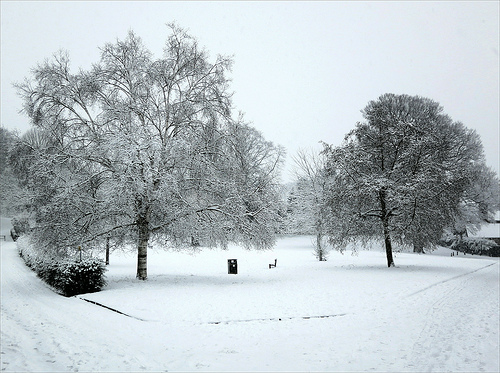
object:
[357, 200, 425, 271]
branch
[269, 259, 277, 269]
bench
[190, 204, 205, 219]
branch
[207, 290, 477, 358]
snow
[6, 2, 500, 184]
sky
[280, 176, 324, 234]
tree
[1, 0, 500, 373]
out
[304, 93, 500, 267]
tree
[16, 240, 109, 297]
bush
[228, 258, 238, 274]
can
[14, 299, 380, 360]
snow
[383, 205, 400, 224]
branch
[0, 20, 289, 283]
tree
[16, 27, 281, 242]
snow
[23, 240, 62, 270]
snow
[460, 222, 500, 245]
house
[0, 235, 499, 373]
ground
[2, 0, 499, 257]
background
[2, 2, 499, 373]
photo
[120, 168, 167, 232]
branch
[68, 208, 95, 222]
branch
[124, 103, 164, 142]
branch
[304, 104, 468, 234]
snow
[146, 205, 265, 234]
branch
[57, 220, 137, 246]
branch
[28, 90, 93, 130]
branch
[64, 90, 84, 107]
branch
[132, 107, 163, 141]
branch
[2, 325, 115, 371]
snow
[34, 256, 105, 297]
snow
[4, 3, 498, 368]
winter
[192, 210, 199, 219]
part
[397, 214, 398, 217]
part